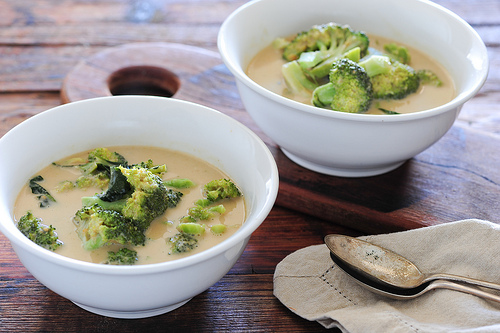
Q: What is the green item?
A: Broccoli.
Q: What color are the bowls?
A: White.